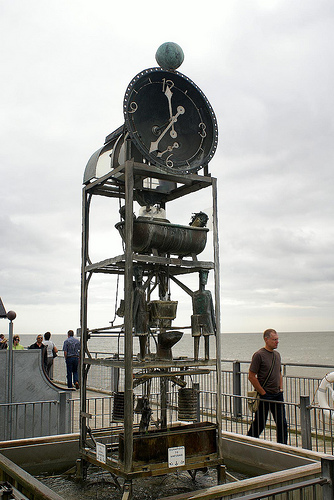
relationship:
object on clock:
[152, 39, 187, 72] [134, 86, 228, 162]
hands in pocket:
[254, 383, 276, 405] [250, 381, 301, 406]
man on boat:
[246, 328, 288, 444] [19, 347, 254, 499]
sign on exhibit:
[153, 450, 210, 471] [99, 119, 254, 491]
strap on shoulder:
[249, 347, 295, 399] [243, 345, 282, 373]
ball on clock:
[149, 36, 222, 83] [134, 86, 228, 162]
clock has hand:
[134, 86, 228, 162] [153, 80, 196, 113]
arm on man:
[235, 358, 303, 423] [206, 290, 325, 414]